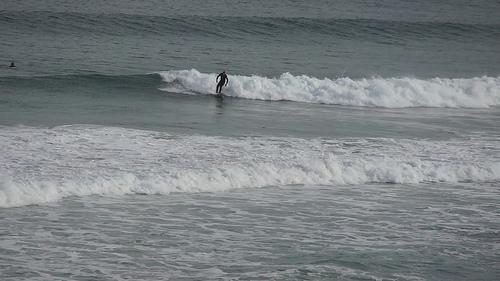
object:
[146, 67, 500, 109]
wave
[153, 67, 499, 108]
foam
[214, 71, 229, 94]
man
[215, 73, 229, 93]
wetsuit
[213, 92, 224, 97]
surfboard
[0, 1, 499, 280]
water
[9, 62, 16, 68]
man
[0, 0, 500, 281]
background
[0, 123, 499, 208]
wave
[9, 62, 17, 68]
head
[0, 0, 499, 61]
reflection